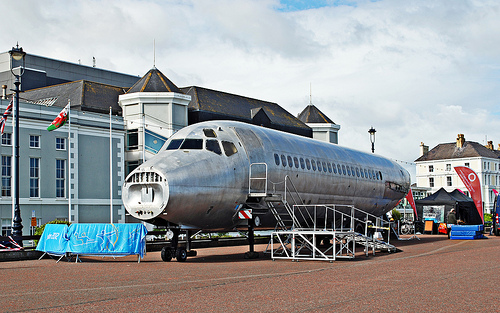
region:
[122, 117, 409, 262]
airplane is missing parts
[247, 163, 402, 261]
ramp leads up to airplane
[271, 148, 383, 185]
windows are in a row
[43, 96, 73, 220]
welsh flag waves in the wind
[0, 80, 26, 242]
union jack waves in the wind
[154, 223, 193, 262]
wheels are attached to the plane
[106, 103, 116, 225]
flag pole has no flag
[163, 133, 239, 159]
no pilots are visibile behind the windows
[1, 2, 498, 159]
it is a very cloudy day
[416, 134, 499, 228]
building is in the background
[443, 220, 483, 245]
Blue boxes on the ground.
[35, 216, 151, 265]
Blue sign on the ground.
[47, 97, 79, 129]
Flag hanging from pole.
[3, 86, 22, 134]
American flag blowing.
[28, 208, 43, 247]
Small red sign on side of road.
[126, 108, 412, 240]
Big silver plane on tarp.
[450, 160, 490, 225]
Red sign standing up.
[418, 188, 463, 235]
Black tent in the back.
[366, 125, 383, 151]
Light post in the back.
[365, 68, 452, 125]
Cloudy sky in the back.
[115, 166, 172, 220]
airplane on display without propeller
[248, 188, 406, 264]
steps leading up to airplane on display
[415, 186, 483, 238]
black tents behind airplane display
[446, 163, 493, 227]
red and white advertising flag behind display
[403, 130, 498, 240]
white building with three chimneys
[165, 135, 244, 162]
cockpit of airplane on display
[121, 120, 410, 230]
airplane on display without it's wings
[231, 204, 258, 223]
red and white sign on underside of plane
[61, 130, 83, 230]
painted white and gray trim on building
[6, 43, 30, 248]
tall street lamp on side of street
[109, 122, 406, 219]
Old passager plane on exhibit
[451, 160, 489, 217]
Red flag at the end of the plane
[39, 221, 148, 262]
Blue cloth at the front of the plane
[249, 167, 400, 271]
Steps leading to the inside of plane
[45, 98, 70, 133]
Red and green flag on the pole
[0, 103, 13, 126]
Brithia flag flying at the lamp post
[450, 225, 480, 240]
Blue pads at the end of the plane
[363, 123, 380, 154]
Street lamp in the distance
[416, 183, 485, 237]
Black tent at the rear of the plane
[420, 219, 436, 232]
Orange sign on the black tent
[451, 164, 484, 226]
Tall and narrow red sign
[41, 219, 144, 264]
The sign is blue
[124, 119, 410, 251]
Part of an airplane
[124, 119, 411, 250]
The airplane is silver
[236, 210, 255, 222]
Red and white striped sign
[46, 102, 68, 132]
The flag is red, green and white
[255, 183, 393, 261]
Silver steps up to the airplane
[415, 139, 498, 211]
The house is yellow with a brown roof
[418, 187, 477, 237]
The tent is black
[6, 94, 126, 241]
The building is pale blue